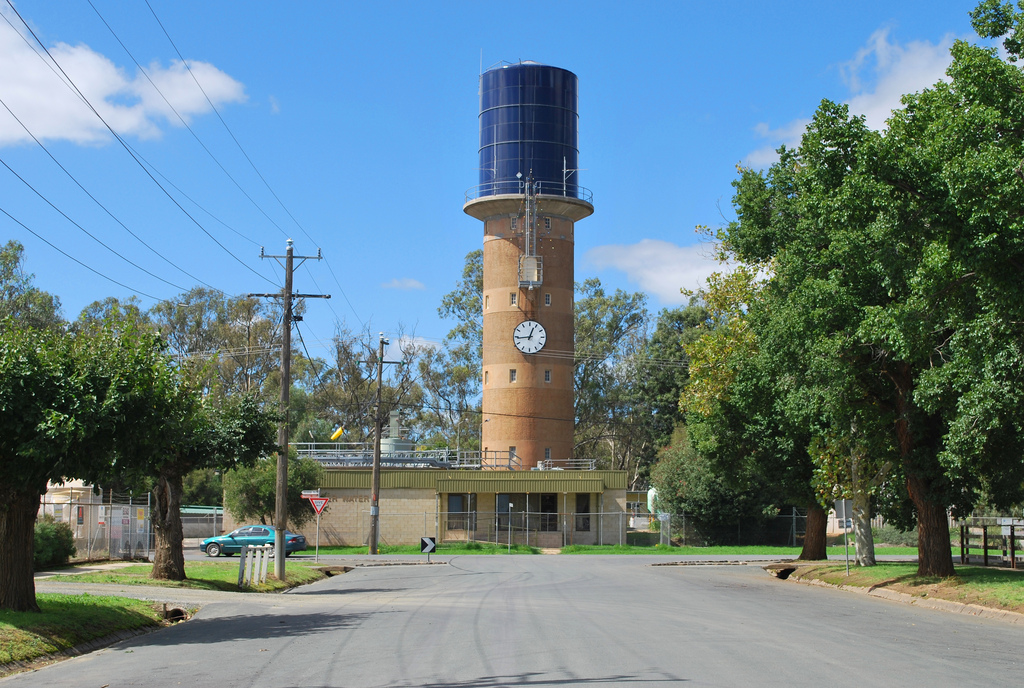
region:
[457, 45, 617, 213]
the blue water tower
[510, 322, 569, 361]
the white and black clock on the tower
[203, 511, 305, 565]
the teal car parked on the street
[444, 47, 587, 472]
the entire water tower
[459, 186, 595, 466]
the brick section of the tower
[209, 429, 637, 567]
the low building in front of the tower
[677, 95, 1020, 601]
the group of trees in the right side of the road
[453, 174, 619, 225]
The railing around the tower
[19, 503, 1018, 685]
the street going into the tower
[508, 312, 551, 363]
a clock on the water tower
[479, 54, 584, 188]
the top of the tower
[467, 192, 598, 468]
the oblong brick tower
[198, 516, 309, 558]
a green car parked along the side of the road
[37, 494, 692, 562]
the fencing arond the facility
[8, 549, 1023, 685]
the paved road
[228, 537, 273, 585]
the short posts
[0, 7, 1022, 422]
the cloudy sky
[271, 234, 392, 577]
the telegram poles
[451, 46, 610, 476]
tan and blue clock tower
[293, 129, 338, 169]
white clouds in blue sky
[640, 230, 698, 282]
white clouds in blue sky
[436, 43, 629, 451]
tall brown clock tower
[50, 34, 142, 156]
white clouds in blue sky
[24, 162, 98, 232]
white clouds in blue sky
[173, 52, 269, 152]
white clouds in blue sky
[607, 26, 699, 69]
white clouds in blue sky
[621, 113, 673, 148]
white clouds in blue sky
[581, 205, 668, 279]
white clouds in blue sky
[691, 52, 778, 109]
white clouds in blue sky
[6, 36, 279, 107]
blue and white sky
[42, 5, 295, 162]
white clouds in sky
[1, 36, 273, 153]
thin clouds in sky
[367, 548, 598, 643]
road is light grey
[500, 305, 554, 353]
white face on clock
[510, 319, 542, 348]
black hands on clock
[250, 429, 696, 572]
brown building at end of road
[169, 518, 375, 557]
green car is parked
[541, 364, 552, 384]
glass is clean and clear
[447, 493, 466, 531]
glass is clean and clear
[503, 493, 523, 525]
glass is clean and clear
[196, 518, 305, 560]
teal car parked beside a building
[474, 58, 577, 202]
dark blue tower on tob of brown building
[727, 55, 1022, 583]
large green tree besid gray road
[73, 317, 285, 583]
large green tree besid gray road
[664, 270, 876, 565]
large green tree besid gray road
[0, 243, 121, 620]
large green tree besid gray road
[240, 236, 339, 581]
tall brown wooden utility pole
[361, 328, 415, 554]
tall brown wooden utility pole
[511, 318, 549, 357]
white clock face on side of building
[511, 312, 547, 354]
round white clock with black numerals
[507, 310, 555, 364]
round clock on tower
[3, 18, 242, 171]
white cloud in sky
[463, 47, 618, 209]
blue top on tower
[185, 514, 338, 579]
green car in front of building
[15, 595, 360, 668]
shadow of tree on road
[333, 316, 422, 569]
power pole in front of building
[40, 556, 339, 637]
driveway coming into street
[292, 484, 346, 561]
red and white sign on street corner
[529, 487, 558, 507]
building has a window